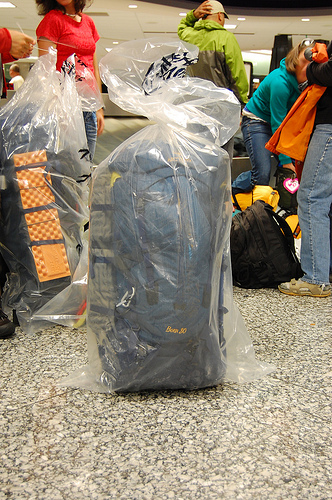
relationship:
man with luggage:
[178, 0, 249, 118] [1, 80, 302, 393]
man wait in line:
[178, 0, 249, 118] [2, 1, 321, 308]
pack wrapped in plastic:
[0, 103, 74, 293] [0, 43, 86, 331]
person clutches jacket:
[277, 31, 331, 298] [263, 48, 329, 162]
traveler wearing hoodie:
[231, 42, 319, 192] [245, 56, 305, 166]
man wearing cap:
[178, 0, 249, 118] [198, 0, 228, 18]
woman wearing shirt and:
[35, 0, 104, 162] [35, 9, 100, 162]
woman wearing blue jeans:
[35, 0, 104, 162] [77, 108, 98, 167]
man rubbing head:
[178, 0, 249, 118] [197, 0, 224, 26]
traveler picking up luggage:
[231, 40, 312, 198] [279, 165, 302, 231]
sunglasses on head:
[299, 39, 316, 46] [196, 2, 229, 29]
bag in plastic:
[88, 125, 229, 396] [53, 35, 280, 396]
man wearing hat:
[178, 0, 249, 118] [195, 0, 234, 20]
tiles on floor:
[1, 337, 313, 498] [178, 401, 294, 462]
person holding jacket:
[274, 31, 330, 298] [263, 48, 329, 162]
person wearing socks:
[277, 31, 331, 298] [283, 282, 329, 290]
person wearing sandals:
[277, 31, 331, 298] [278, 275, 331, 297]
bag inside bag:
[88, 125, 229, 396] [72, 73, 263, 435]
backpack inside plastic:
[229, 194, 302, 289] [0, 46, 106, 338]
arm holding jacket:
[305, 39, 323, 153] [264, 35, 321, 166]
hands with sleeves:
[7, 29, 36, 63] [0, 26, 11, 62]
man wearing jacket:
[178, 0, 249, 118] [165, 10, 257, 109]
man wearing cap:
[174, 7, 265, 177] [192, 1, 236, 20]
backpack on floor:
[229, 199, 302, 288] [0, 284, 331, 498]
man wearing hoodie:
[178, 0, 249, 118] [245, 54, 305, 166]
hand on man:
[194, 1, 212, 18] [178, 0, 249, 118]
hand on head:
[194, 1, 212, 18] [197, 0, 227, 23]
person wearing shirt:
[5, 62, 27, 96] [30, 13, 114, 99]